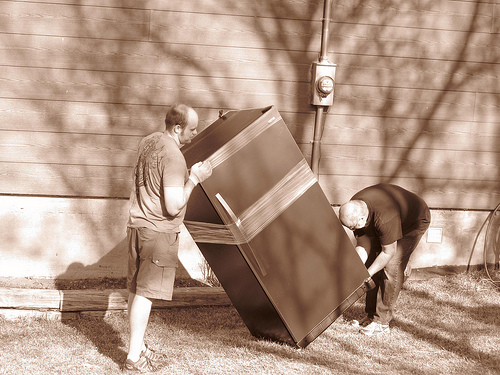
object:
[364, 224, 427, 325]
pants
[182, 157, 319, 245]
tape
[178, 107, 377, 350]
fridge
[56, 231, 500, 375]
cast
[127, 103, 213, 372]
man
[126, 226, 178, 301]
shorts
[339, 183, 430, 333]
man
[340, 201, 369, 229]
head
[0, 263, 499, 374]
ground